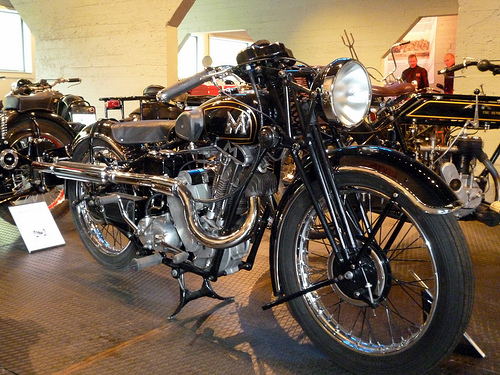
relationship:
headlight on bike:
[313, 56, 375, 135] [32, 39, 499, 374]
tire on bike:
[67, 119, 148, 273] [32, 39, 499, 374]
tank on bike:
[184, 102, 261, 154] [32, 39, 499, 374]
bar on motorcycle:
[159, 60, 237, 110] [62, 36, 482, 371]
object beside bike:
[13, 200, 59, 252] [38, 43, 446, 353]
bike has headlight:
[32, 39, 499, 374] [317, 57, 374, 132]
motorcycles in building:
[1, 37, 498, 373] [4, 12, 498, 370]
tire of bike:
[271, 136, 484, 373] [32, 39, 499, 374]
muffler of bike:
[24, 156, 176, 236] [32, 39, 499, 374]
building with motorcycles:
[4, 12, 498, 370] [81, 16, 482, 371]